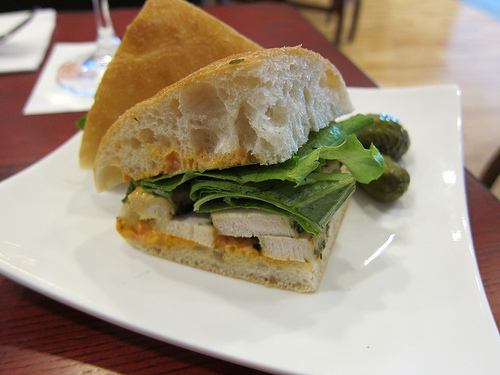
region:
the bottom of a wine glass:
[46, 3, 126, 90]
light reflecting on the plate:
[439, 163, 460, 190]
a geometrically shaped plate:
[0, 72, 486, 368]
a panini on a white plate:
[57, 0, 427, 314]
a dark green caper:
[361, 158, 414, 199]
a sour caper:
[366, 113, 408, 150]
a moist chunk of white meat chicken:
[260, 234, 317, 263]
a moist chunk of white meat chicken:
[214, 212, 289, 237]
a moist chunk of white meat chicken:
[169, 213, 207, 241]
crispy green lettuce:
[200, 174, 339, 210]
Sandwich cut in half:
[68, 1, 415, 299]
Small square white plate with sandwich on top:
[0, 61, 499, 374]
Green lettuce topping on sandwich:
[140, 103, 390, 240]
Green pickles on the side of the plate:
[340, 104, 424, 218]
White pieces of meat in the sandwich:
[137, 174, 344, 287]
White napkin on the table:
[23, 13, 133, 128]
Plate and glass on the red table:
[2, 7, 498, 372]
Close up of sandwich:
[82, 1, 363, 301]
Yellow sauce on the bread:
[115, 221, 305, 272]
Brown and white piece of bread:
[76, 48, 363, 183]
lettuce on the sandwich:
[347, 152, 382, 174]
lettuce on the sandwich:
[280, 189, 325, 230]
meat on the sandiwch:
[265, 233, 305, 257]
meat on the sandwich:
[219, 207, 286, 235]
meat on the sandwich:
[181, 220, 218, 235]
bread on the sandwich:
[161, 73, 289, 133]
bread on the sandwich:
[227, 268, 328, 273]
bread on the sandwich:
[169, 110, 229, 154]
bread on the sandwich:
[126, 13, 221, 59]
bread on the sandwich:
[108, 223, 163, 260]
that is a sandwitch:
[88, 37, 362, 274]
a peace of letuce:
[303, 174, 341, 229]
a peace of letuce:
[327, 128, 377, 181]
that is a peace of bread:
[116, 70, 314, 174]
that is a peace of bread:
[111, 219, 311, 271]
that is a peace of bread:
[126, 7, 193, 83]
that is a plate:
[366, 277, 426, 354]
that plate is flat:
[332, 262, 409, 328]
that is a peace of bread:
[3, 325, 24, 360]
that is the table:
[263, 7, 291, 44]